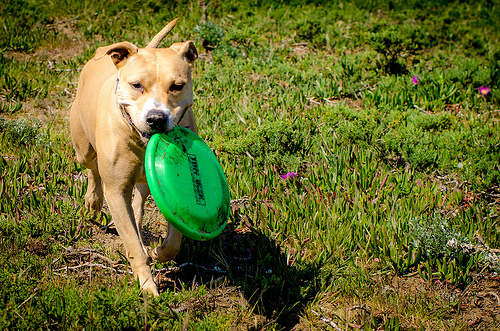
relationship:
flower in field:
[474, 85, 484, 99] [2, 0, 483, 328]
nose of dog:
[143, 105, 170, 133] [65, 15, 199, 305]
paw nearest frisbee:
[144, 236, 184, 262] [144, 126, 233, 241]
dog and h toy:
[65, 15, 199, 305] [140, 123, 233, 242]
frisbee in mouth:
[144, 126, 233, 241] [117, 103, 193, 153]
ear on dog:
[90, 39, 140, 70] [65, 15, 199, 305]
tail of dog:
[144, 14, 182, 49] [65, 15, 199, 305]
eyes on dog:
[127, 78, 187, 94] [65, 15, 199, 305]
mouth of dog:
[117, 103, 193, 153] [65, 15, 199, 305]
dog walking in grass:
[65, 15, 199, 305] [2, 0, 482, 329]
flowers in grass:
[408, 70, 484, 97] [2, 0, 482, 329]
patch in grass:
[19, 16, 96, 60] [2, 0, 482, 329]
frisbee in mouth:
[144, 126, 233, 241] [118, 103, 193, 148]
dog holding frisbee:
[65, 15, 199, 305] [144, 126, 233, 241]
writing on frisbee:
[184, 147, 209, 206] [144, 126, 233, 241]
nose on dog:
[141, 111, 173, 135] [62, 13, 222, 312]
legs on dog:
[95, 152, 168, 306] [62, 13, 222, 312]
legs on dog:
[152, 209, 195, 260] [62, 13, 222, 312]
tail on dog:
[137, 12, 183, 44] [65, 10, 216, 300]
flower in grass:
[407, 69, 421, 88] [2, 0, 482, 329]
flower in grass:
[479, 81, 491, 102] [2, 0, 482, 329]